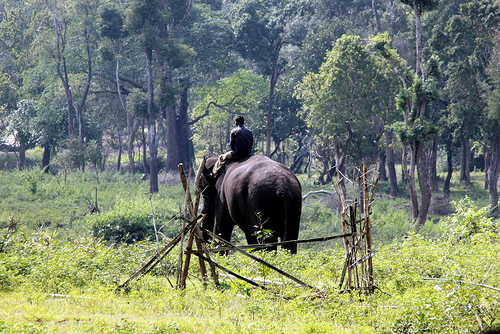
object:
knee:
[215, 152, 227, 164]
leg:
[206, 150, 236, 184]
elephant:
[185, 147, 307, 255]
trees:
[398, 0, 476, 235]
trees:
[304, 28, 416, 290]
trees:
[125, 2, 185, 189]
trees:
[49, 1, 96, 182]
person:
[208, 110, 254, 164]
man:
[221, 110, 266, 234]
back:
[236, 136, 248, 142]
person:
[210, 115, 254, 177]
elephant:
[181, 149, 308, 264]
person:
[204, 114, 254, 176]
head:
[233, 114, 248, 123]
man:
[212, 109, 261, 171]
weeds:
[0, 165, 499, 331]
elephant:
[193, 153, 303, 251]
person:
[207, 114, 258, 185]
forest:
[4, 2, 493, 219]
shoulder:
[243, 127, 251, 137]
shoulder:
[230, 125, 237, 135]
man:
[227, 115, 257, 158]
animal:
[193, 148, 301, 247]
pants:
[209, 151, 229, 175]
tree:
[383, 0, 435, 225]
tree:
[422, 0, 499, 217]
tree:
[418, 25, 455, 195]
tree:
[235, 17, 302, 151]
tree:
[129, 0, 205, 193]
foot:
[206, 172, 216, 179]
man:
[205, 116, 252, 179]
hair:
[233, 113, 243, 124]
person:
[207, 115, 260, 177]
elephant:
[154, 153, 308, 244]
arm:
[190, 147, 302, 262]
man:
[205, 112, 255, 179]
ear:
[176, 150, 210, 189]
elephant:
[138, 150, 353, 262]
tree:
[300, 37, 394, 215]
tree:
[97, 5, 204, 197]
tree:
[232, 0, 297, 163]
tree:
[5, 5, 95, 167]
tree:
[429, 7, 486, 195]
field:
[1, 165, 498, 332]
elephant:
[194, 147, 306, 258]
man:
[210, 116, 253, 179]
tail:
[276, 186, 289, 245]